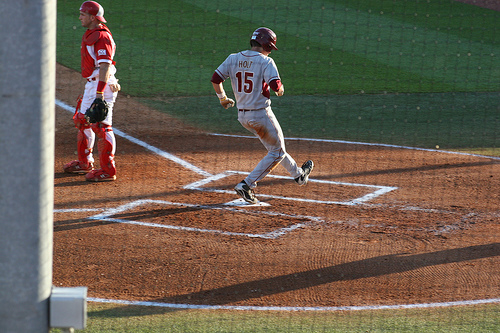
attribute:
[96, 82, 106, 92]
sweatband — orange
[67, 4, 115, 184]
catcher — not paying attention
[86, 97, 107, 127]
baseball mitt — black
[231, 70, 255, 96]
number — red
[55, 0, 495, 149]
grass — green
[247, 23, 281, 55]
helmet — maroon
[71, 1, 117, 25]
helmet — maroon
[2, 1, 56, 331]
pole — silver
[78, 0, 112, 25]
hat — red and white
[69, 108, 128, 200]
shin pads — red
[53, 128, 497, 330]
soil — red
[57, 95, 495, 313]
marks — white, chalk